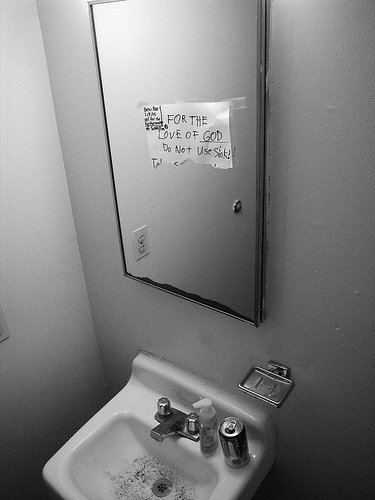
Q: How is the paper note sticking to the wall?
A: With tape.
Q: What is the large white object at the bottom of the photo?
A: Sink.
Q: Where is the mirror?
A: Hanging on the wall.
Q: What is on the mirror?
A: A handwritten note.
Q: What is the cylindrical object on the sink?
A: Soda can.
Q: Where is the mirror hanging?
A: Above the sink.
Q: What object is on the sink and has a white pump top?
A: Liquid soap dispenser.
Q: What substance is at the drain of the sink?
A: Dirt.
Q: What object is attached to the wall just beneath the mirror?
A: A soap holder.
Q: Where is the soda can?
A: On the sink.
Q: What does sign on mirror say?
A: Do not use sink.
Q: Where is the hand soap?
A: Next to faucet.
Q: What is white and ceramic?
A: Sink.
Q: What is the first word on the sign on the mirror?
A: For.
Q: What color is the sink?
A: White.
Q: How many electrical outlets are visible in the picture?
A: One.